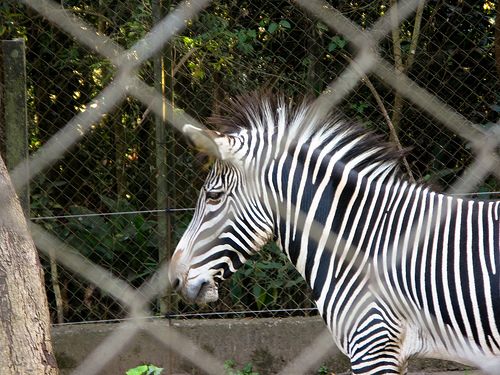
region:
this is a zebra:
[192, 92, 485, 373]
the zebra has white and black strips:
[298, 146, 348, 263]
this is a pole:
[0, 24, 34, 172]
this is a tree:
[208, 32, 310, 89]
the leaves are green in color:
[196, 13, 250, 55]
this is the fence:
[103, 110, 191, 218]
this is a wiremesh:
[83, 138, 128, 194]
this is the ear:
[173, 124, 226, 161]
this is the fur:
[299, 105, 347, 152]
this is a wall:
[216, 311, 269, 353]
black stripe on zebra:
[206, 260, 234, 278]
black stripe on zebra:
[188, 249, 241, 271]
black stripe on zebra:
[193, 237, 248, 257]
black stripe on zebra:
[190, 211, 262, 250]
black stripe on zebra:
[351, 358, 396, 372]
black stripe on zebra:
[351, 332, 391, 354]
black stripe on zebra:
[471, 200, 493, 351]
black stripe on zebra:
[461, 199, 483, 353]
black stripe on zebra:
[446, 198, 469, 351]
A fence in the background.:
[44, 71, 156, 191]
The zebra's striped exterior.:
[317, 202, 439, 310]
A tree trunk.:
[0, 183, 67, 365]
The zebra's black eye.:
[199, 181, 234, 218]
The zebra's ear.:
[165, 110, 250, 165]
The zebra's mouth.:
[182, 279, 228, 309]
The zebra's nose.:
[162, 272, 187, 293]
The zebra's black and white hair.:
[207, 83, 420, 173]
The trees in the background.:
[83, 5, 316, 97]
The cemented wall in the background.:
[72, 318, 295, 363]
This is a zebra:
[158, 78, 490, 373]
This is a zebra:
[163, 82, 495, 367]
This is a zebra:
[165, 88, 493, 367]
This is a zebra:
[154, 85, 496, 352]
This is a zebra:
[160, 96, 496, 353]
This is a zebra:
[168, 82, 495, 349]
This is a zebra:
[155, 102, 497, 347]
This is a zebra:
[158, 82, 498, 362]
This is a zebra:
[148, 85, 498, 339]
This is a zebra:
[137, 88, 497, 370]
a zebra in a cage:
[167, 99, 489, 373]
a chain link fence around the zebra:
[11, 39, 493, 332]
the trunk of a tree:
[2, 172, 49, 367]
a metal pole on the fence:
[153, 30, 165, 316]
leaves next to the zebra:
[124, 361, 164, 373]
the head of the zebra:
[164, 108, 286, 305]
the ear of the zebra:
[182, 122, 226, 152]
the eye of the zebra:
[206, 192, 225, 199]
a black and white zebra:
[168, 88, 499, 372]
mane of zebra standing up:
[154, 88, 418, 309]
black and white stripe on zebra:
[300, 160, 350, 301]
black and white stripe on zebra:
[447, 203, 482, 343]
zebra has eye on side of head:
[188, 178, 230, 208]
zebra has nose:
[141, 246, 191, 293]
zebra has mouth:
[186, 270, 216, 309]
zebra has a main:
[219, 94, 412, 184]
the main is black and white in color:
[218, 85, 434, 193]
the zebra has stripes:
[166, 100, 493, 332]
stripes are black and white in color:
[159, 111, 470, 308]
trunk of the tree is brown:
[4, 168, 51, 374]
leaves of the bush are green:
[55, 98, 312, 310]